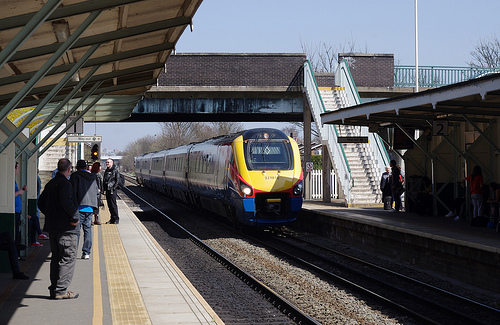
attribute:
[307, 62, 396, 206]
flight — white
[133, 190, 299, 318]
tracks — empty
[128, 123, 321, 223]
train — blue, yellow, white, stopped, red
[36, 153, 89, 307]
person — waiting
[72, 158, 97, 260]
person — waiting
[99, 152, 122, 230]
person — waiting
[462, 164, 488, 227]
person — waiting, red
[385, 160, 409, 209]
person — waiting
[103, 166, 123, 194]
jacket — black, leather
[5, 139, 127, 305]
people — standing, waiting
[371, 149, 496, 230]
people — standing, waiting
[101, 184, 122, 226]
pants — black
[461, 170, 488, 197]
shirt — red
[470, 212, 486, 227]
shoes — dark, red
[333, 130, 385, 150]
sign — hanging, black, white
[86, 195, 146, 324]
line — yellow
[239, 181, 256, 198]
headlight — lit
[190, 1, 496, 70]
sky — blue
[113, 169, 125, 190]
backpack — black